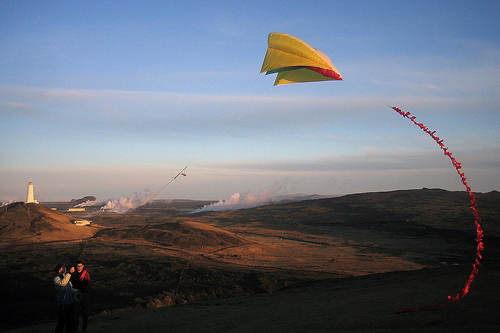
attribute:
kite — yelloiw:
[242, 12, 488, 304]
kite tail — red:
[382, 94, 486, 311]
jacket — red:
[70, 270, 92, 285]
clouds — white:
[7, 71, 499, 201]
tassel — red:
[342, 93, 487, 313]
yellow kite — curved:
[259, 30, 344, 97]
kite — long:
[188, 26, 419, 156]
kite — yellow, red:
[260, 31, 347, 89]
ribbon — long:
[377, 118, 498, 318]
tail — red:
[378, 95, 485, 302]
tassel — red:
[475, 249, 482, 260]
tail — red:
[386, 102, 486, 304]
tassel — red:
[395, 102, 487, 297]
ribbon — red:
[383, 103, 488, 309]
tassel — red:
[456, 170, 466, 177]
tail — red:
[341, 78, 498, 300]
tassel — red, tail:
[402, 112, 410, 118]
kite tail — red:
[385, 88, 469, 200]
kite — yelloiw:
[255, 27, 354, 106]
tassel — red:
[390, 102, 481, 301]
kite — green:
[256, 19, 354, 93]